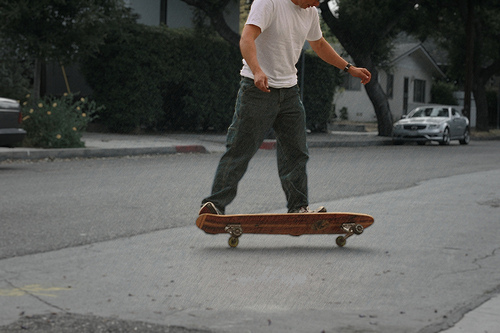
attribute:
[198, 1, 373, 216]
man — skateboading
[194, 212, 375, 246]
skateboard — red, yellow, wooden, brown, long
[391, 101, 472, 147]
car — parked, silver, gray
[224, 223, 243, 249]
wheels — gray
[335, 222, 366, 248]
wheels — gray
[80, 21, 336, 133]
hedges — green, tall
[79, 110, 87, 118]
flower — yellow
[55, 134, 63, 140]
flower — yellow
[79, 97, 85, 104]
flower — yellow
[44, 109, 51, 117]
flower — yellow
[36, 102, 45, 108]
flower — yellow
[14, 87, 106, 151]
plant — green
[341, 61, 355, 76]
watch — black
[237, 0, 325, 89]
shirt — white, short-sleeved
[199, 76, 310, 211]
jeans — blue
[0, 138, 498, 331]
street — paved, gray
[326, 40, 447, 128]
house — white, a-frame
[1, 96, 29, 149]
sedan — black